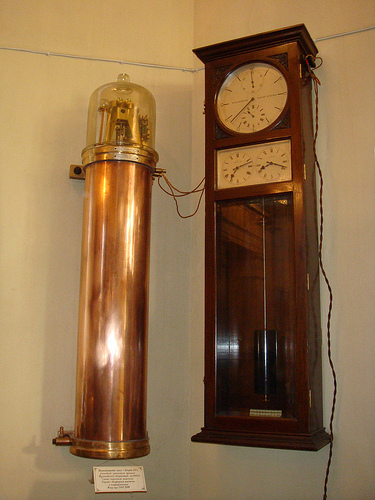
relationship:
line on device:
[249, 69, 253, 88] [52, 23, 332, 459]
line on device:
[262, 67, 270, 78] [213, 61, 289, 133]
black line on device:
[264, 70, 287, 96] [162, 15, 341, 246]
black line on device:
[261, 115, 271, 124] [49, 19, 340, 499]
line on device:
[229, 72, 242, 83] [180, 17, 341, 455]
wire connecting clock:
[158, 173, 206, 220] [191, 21, 332, 451]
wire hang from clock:
[302, 46, 364, 491] [191, 31, 308, 347]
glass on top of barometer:
[66, 61, 179, 174] [52, 73, 160, 459]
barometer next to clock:
[52, 73, 160, 459] [191, 21, 332, 451]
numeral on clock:
[281, 151, 288, 158] [202, 37, 345, 232]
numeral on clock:
[281, 159, 288, 165] [208, 136, 296, 188]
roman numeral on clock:
[272, 98, 288, 111] [213, 58, 296, 145]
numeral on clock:
[276, 169, 282, 178] [191, 21, 332, 451]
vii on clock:
[261, 168, 268, 180] [191, 21, 332, 451]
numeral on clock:
[227, 175, 234, 183] [175, 129, 308, 201]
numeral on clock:
[221, 86, 234, 94] [208, 58, 300, 143]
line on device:
[275, 90, 287, 96] [189, 22, 333, 448]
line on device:
[235, 116, 243, 130] [162, 48, 327, 179]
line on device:
[220, 84, 231, 94] [208, 59, 294, 139]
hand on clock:
[231, 98, 256, 120] [191, 21, 332, 451]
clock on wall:
[185, 21, 346, 460] [193, 1, 374, 498]